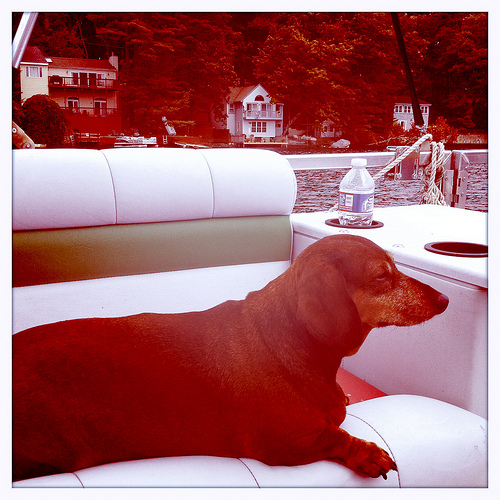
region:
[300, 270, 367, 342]
it is the ear of the dog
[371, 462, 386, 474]
it is the nail of the dog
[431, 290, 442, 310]
it is the nose of the dog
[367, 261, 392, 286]
it is the eye of the dog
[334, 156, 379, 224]
it is a water bottle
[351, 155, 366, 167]
it is the top of the bottle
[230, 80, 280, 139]
a house in the background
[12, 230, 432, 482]
it is a dog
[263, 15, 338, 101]
trees in the background beside the lake and house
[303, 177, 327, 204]
it is a body of water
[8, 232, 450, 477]
Brown dog with gray around muzzle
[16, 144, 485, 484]
Dog sitting on boat seat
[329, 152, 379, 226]
Water bottle with blue and red label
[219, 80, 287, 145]
White two story house with balcony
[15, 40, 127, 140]
Tan and brown house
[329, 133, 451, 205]
White rope with frayed end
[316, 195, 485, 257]
Two black cup holders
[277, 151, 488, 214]
Blue, slightly rough lake water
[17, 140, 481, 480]
White seat with green stripe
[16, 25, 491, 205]
Tall trees lining water way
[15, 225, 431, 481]
An older daschund dog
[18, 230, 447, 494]
A daschund laying on a cushion on a boat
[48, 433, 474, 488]
A white boat cushion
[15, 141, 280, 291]
The back of a seat cushion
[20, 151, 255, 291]
Green and white cushion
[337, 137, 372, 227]
A clear water bottle with a blue label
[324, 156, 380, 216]
A white top on a water bottle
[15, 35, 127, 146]
A large house behind boat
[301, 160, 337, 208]
Water with ripples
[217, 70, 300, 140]
A white house with a brown roof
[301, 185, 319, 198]
wave in the water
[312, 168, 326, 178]
wave in the water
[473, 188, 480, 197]
wave in the water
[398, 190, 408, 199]
wave in the water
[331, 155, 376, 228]
bottle of water in the holder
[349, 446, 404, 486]
paw of the dog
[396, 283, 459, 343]
nose of the dog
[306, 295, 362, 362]
ear of the dog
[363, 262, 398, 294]
eye of the dog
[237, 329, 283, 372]
wrinkle on dog's back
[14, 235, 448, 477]
a long pudgy brown and black hot dog dog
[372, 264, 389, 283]
the black eye of a dog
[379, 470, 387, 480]
the long black claw of a dog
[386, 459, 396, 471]
the long black claw of a dog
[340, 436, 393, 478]
the brown paw of a dog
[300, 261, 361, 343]
the long brown ear of a dog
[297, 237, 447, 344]
the brown head of a dog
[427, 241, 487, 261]
the cup holder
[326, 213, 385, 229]
the black cup holder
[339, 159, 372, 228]
a clear plastic bottle